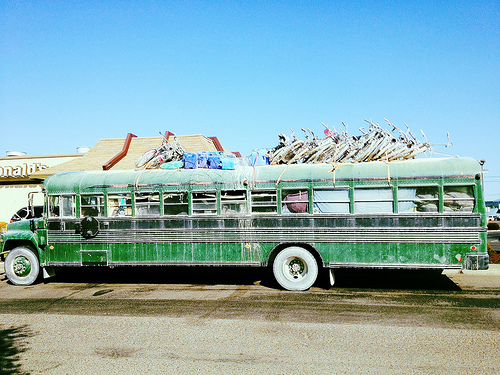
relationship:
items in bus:
[278, 182, 475, 210] [0, 156, 490, 291]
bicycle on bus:
[359, 118, 389, 163] [0, 156, 490, 291]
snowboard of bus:
[272, 246, 319, 292] [9, 159, 494, 311]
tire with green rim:
[6, 244, 40, 290] [12, 255, 31, 277]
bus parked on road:
[0, 156, 490, 291] [1, 263, 498, 373]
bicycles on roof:
[135, 130, 186, 171] [42, 156, 490, 192]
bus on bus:
[0, 156, 490, 291] [0, 156, 490, 291]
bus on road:
[0, 156, 490, 291] [1, 263, 498, 373]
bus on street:
[0, 156, 490, 291] [1, 248, 498, 373]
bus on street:
[0, 156, 490, 291] [6, 268, 498, 368]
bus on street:
[9, 172, 481, 282] [41, 282, 470, 326]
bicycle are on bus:
[359, 118, 389, 163] [0, 156, 490, 291]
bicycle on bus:
[359, 118, 389, 163] [16, 143, 498, 310]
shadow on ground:
[1, 315, 35, 373] [2, 309, 92, 373]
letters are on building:
[4, 160, 52, 176] [28, 88, 294, 310]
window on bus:
[51, 197, 73, 215] [2, 164, 495, 300]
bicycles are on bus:
[135, 122, 437, 165] [0, 156, 490, 291]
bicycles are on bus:
[135, 130, 186, 171] [0, 156, 490, 291]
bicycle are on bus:
[269, 127, 297, 164] [0, 156, 490, 291]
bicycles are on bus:
[398, 125, 448, 160] [0, 156, 490, 291]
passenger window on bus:
[77, 195, 108, 218] [0, 156, 490, 291]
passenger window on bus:
[134, 188, 161, 221] [0, 156, 490, 291]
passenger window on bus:
[157, 187, 192, 219] [0, 156, 490, 291]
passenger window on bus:
[218, 187, 249, 219] [0, 156, 490, 291]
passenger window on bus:
[310, 186, 352, 216] [0, 156, 490, 291]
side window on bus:
[25, 186, 43, 215] [14, 156, 461, 294]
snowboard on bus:
[272, 246, 319, 292] [0, 156, 490, 291]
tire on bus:
[4, 246, 39, 285] [26, 170, 463, 295]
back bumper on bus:
[461, 250, 491, 276] [8, 166, 495, 288]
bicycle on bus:
[264, 130, 318, 164] [0, 156, 490, 291]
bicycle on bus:
[294, 127, 341, 160] [0, 156, 490, 291]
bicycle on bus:
[309, 129, 349, 158] [0, 156, 490, 291]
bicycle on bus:
[335, 124, 389, 159] [0, 156, 490, 291]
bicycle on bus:
[368, 128, 417, 160] [0, 156, 490, 291]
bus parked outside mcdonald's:
[0, 156, 490, 291] [0, 130, 226, 218]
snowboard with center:
[272, 246, 319, 292] [284, 254, 305, 277]